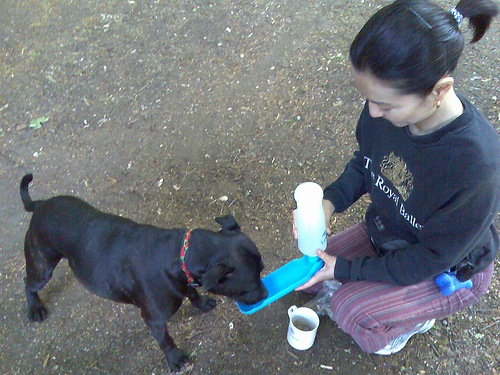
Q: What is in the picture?
A: A dog.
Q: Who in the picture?
A: A woman.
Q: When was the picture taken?
A: Daytime.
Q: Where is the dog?
A: Standing on ground.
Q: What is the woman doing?
A: Giving the dog water.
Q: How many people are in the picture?
A: One.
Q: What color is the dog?
A: Black.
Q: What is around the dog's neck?
A: A collar.